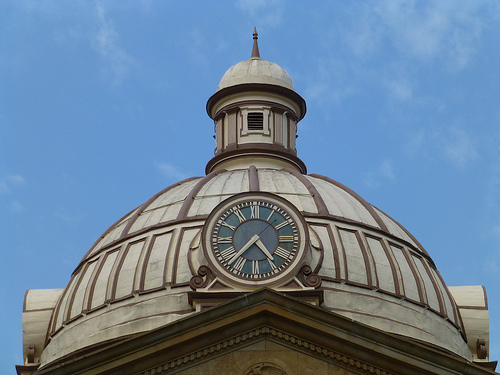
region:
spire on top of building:
[250, 27, 260, 56]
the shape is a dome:
[217, 59, 292, 90]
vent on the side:
[246, 110, 263, 130]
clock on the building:
[202, 190, 309, 287]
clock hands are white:
[228, 233, 273, 261]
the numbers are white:
[214, 200, 296, 276]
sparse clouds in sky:
[1, 0, 498, 268]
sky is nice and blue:
[0, 0, 497, 374]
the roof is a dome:
[41, 165, 474, 363]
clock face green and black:
[215, 203, 295, 281]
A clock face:
[186, 176, 330, 304]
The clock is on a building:
[15, 32, 488, 339]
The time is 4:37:
[187, 181, 330, 295]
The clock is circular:
[185, 175, 329, 300]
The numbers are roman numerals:
[195, 183, 319, 288]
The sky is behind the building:
[10, 12, 477, 160]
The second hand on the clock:
[250, 207, 285, 238]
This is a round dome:
[42, 148, 460, 359]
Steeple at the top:
[240, 20, 265, 67]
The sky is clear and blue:
[21, 22, 180, 173]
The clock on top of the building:
[197, 188, 310, 291]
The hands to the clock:
[225, 230, 277, 268]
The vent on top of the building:
[242, 105, 269, 135]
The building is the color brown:
[320, 183, 436, 348]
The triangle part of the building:
[44, 289, 483, 373]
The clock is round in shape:
[202, 185, 311, 291]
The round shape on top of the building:
[32, 150, 489, 371]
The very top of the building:
[236, 20, 270, 70]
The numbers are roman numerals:
[213, 201, 298, 278]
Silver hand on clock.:
[256, 242, 276, 257]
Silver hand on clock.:
[233, 224, 256, 263]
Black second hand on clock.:
[259, 211, 279, 242]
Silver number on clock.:
[271, 240, 299, 262]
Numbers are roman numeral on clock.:
[216, 198, 300, 296]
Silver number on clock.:
[221, 251, 238, 261]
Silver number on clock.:
[228, 205, 257, 232]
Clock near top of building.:
[198, 190, 303, 290]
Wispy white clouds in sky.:
[385, 93, 430, 121]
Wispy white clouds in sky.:
[367, 159, 405, 188]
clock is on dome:
[205, 193, 310, 288]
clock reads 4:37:
[198, 188, 311, 293]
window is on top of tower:
[241, 106, 269, 135]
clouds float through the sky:
[5, 3, 495, 190]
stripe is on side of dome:
[324, 217, 348, 282]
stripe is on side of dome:
[352, 224, 384, 288]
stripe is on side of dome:
[378, 233, 404, 300]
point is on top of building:
[250, 26, 262, 58]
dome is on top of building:
[23, 21, 493, 371]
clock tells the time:
[199, 191, 310, 288]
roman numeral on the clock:
[272, 223, 289, 227]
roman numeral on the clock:
[264, 223, 312, 244]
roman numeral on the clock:
[273, 241, 298, 262]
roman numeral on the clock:
[261, 245, 276, 281]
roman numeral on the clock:
[253, 251, 258, 278]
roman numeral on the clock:
[234, 249, 248, 274]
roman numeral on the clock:
[212, 221, 237, 239]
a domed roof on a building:
[40, 168, 475, 369]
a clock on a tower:
[199, 192, 311, 292]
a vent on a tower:
[245, 112, 264, 130]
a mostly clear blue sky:
[1, 0, 498, 373]